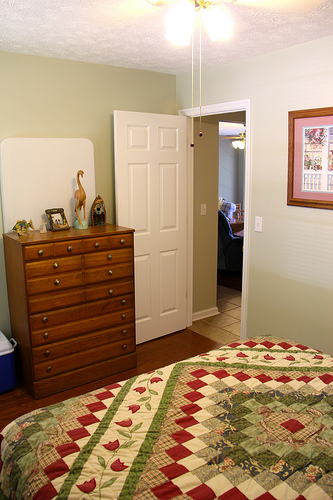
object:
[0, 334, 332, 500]
quilt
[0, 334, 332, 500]
bed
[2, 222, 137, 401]
chest of drawers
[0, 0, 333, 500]
room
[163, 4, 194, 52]
lamps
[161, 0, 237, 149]
ceiling fan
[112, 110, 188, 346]
door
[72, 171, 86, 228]
dinosaur models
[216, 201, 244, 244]
man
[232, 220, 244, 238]
book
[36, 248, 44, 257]
brass knobs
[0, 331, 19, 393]
blue cooler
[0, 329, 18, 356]
white lid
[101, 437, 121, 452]
red flowers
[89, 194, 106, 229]
fish figurine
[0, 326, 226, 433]
wooden floor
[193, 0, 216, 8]
light fixtures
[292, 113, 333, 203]
picture on wall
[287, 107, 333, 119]
wooden frame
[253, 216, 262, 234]
light switch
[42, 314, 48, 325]
brass handle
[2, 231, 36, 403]
golden frame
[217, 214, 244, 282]
recliner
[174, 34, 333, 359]
wall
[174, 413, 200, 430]
red patch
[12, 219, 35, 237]
decorative bird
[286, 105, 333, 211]
wooden picture frame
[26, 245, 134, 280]
drawer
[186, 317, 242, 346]
tile flooring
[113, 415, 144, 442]
flower prints